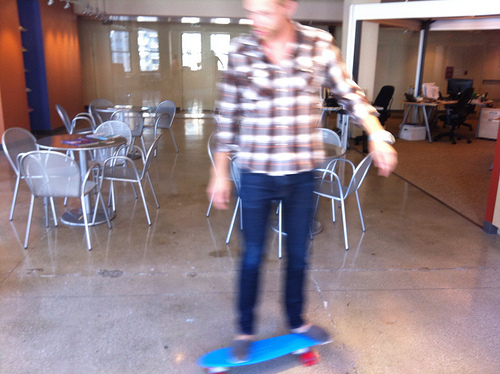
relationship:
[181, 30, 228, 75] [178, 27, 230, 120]
two windows on door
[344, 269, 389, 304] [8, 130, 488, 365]
tile on floor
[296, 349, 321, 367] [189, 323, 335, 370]
wheel on skateboard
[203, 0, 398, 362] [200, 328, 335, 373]
man riding skateboard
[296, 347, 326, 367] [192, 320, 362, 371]
wheel of skateboard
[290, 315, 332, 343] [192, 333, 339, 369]
feet on skateboard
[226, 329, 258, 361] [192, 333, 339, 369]
feet on skateboard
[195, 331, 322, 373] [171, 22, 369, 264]
skateboard under man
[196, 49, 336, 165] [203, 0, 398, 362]
shirt on man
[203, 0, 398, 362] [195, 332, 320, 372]
man on skateboard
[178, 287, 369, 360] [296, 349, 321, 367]
skateboard with wheel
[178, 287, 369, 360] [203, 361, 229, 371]
skateboard with wheels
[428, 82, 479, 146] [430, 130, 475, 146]
office chair on wheels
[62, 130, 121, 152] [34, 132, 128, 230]
books on table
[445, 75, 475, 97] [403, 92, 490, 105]
monitor on desk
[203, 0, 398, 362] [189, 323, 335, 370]
man on skateboard